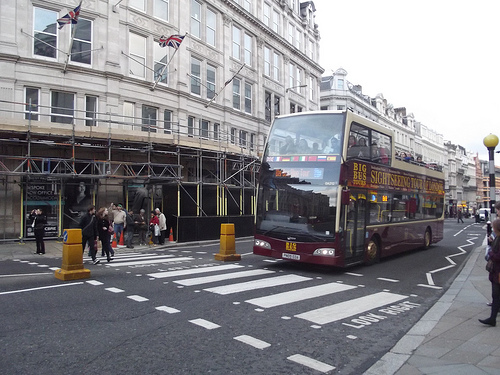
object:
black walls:
[170, 214, 257, 243]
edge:
[340, 171, 349, 189]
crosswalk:
[79, 252, 410, 325]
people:
[278, 134, 389, 156]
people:
[77, 203, 166, 265]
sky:
[314, 0, 498, 131]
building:
[319, 65, 500, 216]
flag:
[56, 0, 87, 31]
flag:
[152, 31, 189, 49]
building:
[0, 0, 325, 243]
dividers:
[52, 222, 241, 282]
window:
[70, 16, 92, 67]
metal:
[1, 141, 246, 218]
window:
[128, 29, 146, 78]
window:
[198, 120, 210, 137]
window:
[206, 10, 216, 46]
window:
[245, 80, 252, 114]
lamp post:
[482, 133, 499, 261]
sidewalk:
[367, 191, 499, 375]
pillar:
[53, 228, 91, 281]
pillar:
[215, 223, 242, 261]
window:
[86, 94, 98, 126]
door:
[346, 186, 367, 263]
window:
[31, 5, 59, 58]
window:
[25, 86, 38, 121]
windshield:
[257, 166, 337, 237]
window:
[122, 100, 134, 133]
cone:
[119, 230, 125, 245]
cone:
[112, 232, 118, 247]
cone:
[169, 227, 175, 241]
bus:
[252, 109, 445, 269]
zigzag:
[424, 233, 478, 287]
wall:
[177, 218, 253, 236]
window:
[49, 90, 75, 125]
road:
[14, 225, 497, 372]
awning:
[0, 122, 258, 161]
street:
[0, 219, 499, 374]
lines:
[11, 260, 340, 375]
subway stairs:
[170, 213, 255, 244]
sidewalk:
[9, 196, 228, 257]